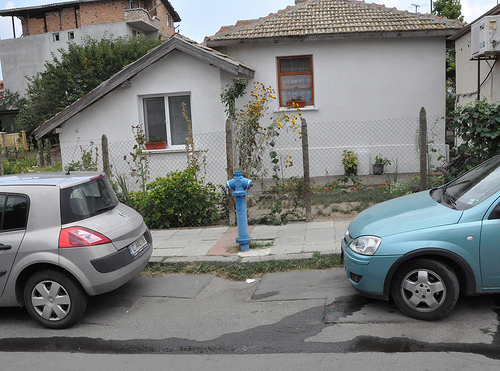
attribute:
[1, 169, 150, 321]
car — Gray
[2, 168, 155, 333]
car — blue, silver 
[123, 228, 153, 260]
license plate — white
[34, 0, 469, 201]
grey house — grey , Small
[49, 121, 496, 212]
metallic fence. — metallic 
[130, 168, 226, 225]
bush — green, small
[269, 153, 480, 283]
car — parked, blue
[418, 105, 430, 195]
post — wood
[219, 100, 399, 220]
fence — wire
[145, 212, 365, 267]
sidewalk — Paved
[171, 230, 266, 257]
sudewalk — in bad shape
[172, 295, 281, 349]
street — in bad shape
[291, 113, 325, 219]
post — wood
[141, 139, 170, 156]
box — brown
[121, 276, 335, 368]
pavement — uneven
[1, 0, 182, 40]
house — Tall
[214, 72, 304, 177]
plant — Tall 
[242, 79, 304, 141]
flowers — yellow 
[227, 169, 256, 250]
fire hydrant — blue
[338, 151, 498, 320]
car — blue